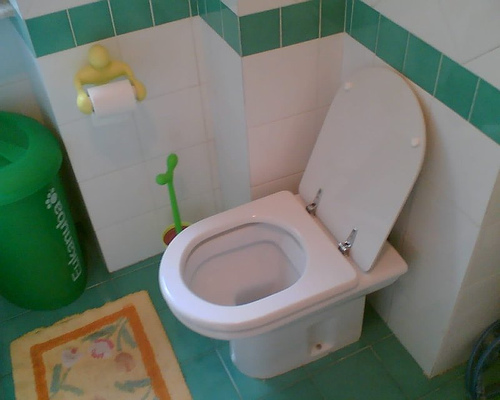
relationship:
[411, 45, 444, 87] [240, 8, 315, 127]
tile on wall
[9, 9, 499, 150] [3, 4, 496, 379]
green tiles on walls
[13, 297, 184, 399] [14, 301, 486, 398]
rug on floor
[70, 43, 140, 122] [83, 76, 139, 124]
holder for toilet paper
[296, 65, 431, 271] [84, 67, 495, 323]
seat cover of toilet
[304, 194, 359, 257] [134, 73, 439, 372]
hardware on toilet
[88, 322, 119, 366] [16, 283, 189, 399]
flower on rug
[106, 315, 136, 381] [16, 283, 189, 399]
flower on rug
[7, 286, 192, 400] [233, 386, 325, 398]
rug on floor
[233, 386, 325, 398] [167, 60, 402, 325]
floor in front of toilet